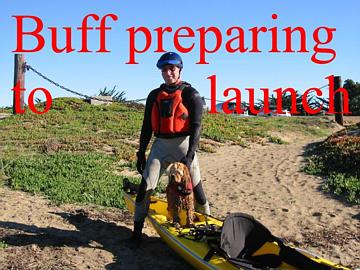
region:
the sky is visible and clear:
[40, 24, 187, 88]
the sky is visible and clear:
[16, 30, 232, 33]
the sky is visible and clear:
[41, 59, 227, 111]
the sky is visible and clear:
[51, 19, 244, 126]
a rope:
[68, 82, 132, 164]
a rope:
[52, 60, 133, 129]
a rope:
[51, 68, 168, 161]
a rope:
[36, 43, 118, 145]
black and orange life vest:
[148, 86, 198, 138]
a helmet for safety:
[155, 51, 183, 69]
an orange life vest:
[149, 81, 191, 136]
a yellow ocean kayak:
[120, 178, 351, 269]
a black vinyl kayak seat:
[220, 212, 278, 269]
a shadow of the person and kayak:
[0, 208, 152, 269]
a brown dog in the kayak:
[166, 162, 196, 228]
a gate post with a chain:
[13, 52, 26, 113]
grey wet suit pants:
[133, 137, 169, 232]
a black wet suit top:
[182, 83, 203, 165]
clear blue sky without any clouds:
[1, 0, 358, 12]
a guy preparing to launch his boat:
[114, 49, 358, 268]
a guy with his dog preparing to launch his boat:
[126, 47, 289, 268]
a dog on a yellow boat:
[160, 156, 193, 254]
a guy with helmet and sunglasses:
[124, 40, 212, 249]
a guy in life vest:
[129, 41, 219, 166]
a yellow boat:
[118, 183, 272, 265]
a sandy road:
[244, 164, 289, 196]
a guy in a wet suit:
[124, 43, 207, 245]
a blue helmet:
[149, 46, 198, 76]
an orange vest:
[138, 83, 197, 140]